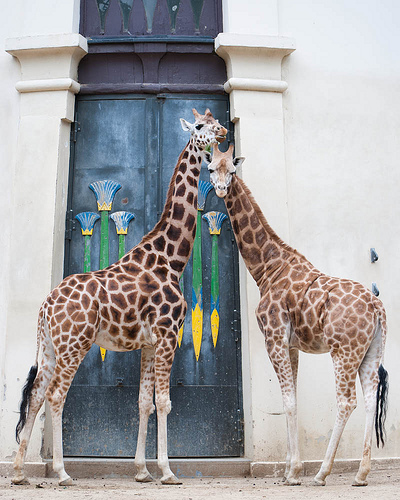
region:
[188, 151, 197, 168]
brown spot on giraffe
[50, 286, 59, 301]
brown spot on giraffe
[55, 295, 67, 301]
brown spot on giraffe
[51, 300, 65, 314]
brown spot on giraffe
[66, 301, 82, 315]
brown spot on giraffe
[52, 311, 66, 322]
brown spot on giraffe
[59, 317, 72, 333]
brown spot on giraffe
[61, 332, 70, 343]
brown spot on giraffe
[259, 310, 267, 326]
brown spot on giraffe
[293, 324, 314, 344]
brown spot on giraffe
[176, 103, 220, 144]
head of the giraffe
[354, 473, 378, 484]
hoof of the giraffe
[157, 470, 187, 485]
head of the giraffe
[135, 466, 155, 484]
hoof of the giraffe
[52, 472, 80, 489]
hoof of the giraffe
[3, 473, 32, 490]
hoof of the giraffe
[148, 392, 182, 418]
knee of the giraffe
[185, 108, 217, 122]
horns of hte giraffe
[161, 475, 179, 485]
hoof of the giraffe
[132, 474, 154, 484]
hoof of the giraffe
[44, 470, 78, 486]
hoof of the giraffe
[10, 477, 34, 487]
hoof of the giraffe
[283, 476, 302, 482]
hoof of the giraffe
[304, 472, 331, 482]
hoof of the giraffe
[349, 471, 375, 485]
hoof of the giraffe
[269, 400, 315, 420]
knee of the giraffe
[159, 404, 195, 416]
knee of the giraffe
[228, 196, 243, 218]
brown spot on giraffe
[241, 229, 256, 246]
brown spot on giraffe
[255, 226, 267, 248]
brown spot on giraffe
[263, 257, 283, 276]
brown spot on giraffe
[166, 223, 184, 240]
brown spot on giraffe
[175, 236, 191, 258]
brown spot on giraffe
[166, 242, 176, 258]
brown spot on giraffe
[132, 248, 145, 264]
brown spot on giraffe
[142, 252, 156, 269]
brown spot on giraffe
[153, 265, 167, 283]
brown spot on giraffe